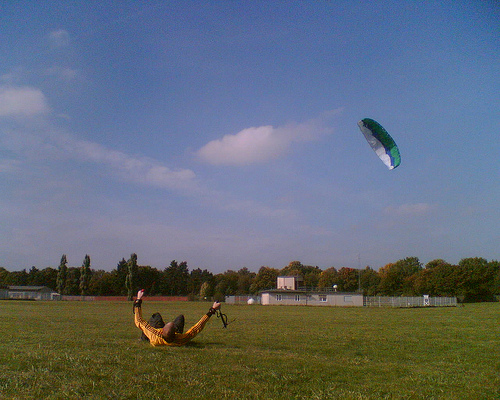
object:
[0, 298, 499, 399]
grass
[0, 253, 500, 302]
trees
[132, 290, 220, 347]
man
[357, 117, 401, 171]
kite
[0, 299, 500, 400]
ground